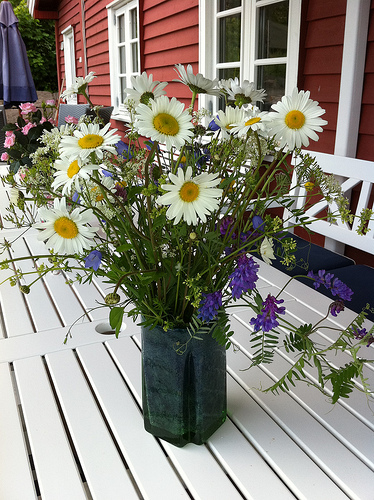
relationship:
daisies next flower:
[156, 166, 223, 227] [124, 91, 198, 157]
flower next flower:
[29, 186, 105, 260] [45, 149, 99, 200]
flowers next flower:
[131, 94, 195, 152] [259, 84, 328, 158]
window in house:
[191, 3, 306, 145] [0, 0, 374, 499]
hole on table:
[89, 318, 125, 338] [16, 173, 373, 499]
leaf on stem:
[108, 303, 128, 339] [119, 295, 133, 309]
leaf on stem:
[264, 331, 280, 340] [259, 323, 265, 355]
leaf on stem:
[286, 367, 296, 388] [274, 360, 299, 383]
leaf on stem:
[282, 379, 291, 392] [274, 363, 297, 386]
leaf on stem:
[294, 162, 303, 178] [297, 160, 310, 185]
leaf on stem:
[149, 163, 163, 179] [142, 153, 150, 192]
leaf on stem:
[350, 326, 358, 335] [342, 319, 354, 335]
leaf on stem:
[264, 334, 280, 350] [259, 325, 267, 359]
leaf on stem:
[249, 332, 262, 342] [259, 328, 268, 360]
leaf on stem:
[248, 338, 260, 350] [257, 329, 266, 357]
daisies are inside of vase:
[76, 85, 311, 274] [147, 298, 219, 430]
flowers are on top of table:
[4, 95, 44, 163] [16, 173, 373, 499]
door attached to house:
[53, 25, 81, 96] [53, 6, 373, 271]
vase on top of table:
[140, 312, 227, 448] [16, 173, 373, 499]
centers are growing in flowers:
[241, 110, 303, 131] [221, 85, 343, 150]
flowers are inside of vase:
[131, 94, 195, 152] [146, 312, 227, 435]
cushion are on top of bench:
[295, 260, 373, 324] [259, 148, 373, 328]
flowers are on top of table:
[67, 83, 275, 289] [16, 173, 373, 499]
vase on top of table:
[140, 312, 227, 448] [6, 195, 373, 488]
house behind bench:
[62, 42, 372, 280] [274, 141, 369, 247]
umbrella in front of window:
[1, 41, 32, 112] [50, 39, 96, 126]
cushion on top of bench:
[265, 229, 372, 302] [270, 140, 372, 309]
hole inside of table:
[95, 318, 122, 338] [16, 173, 373, 499]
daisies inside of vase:
[156, 166, 223, 227] [138, 309, 223, 438]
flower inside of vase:
[195, 282, 218, 316] [140, 312, 227, 448]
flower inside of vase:
[263, 92, 323, 151] [142, 317, 224, 439]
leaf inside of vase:
[108, 303, 124, 340] [138, 309, 223, 438]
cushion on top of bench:
[277, 233, 372, 337] [263, 146, 373, 286]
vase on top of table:
[146, 312, 227, 435] [16, 173, 373, 499]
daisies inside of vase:
[156, 166, 223, 227] [146, 319, 228, 444]